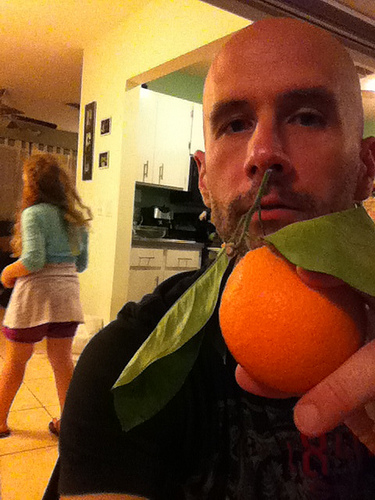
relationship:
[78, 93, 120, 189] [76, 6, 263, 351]
pictures on wall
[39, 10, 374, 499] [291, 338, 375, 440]
man has finger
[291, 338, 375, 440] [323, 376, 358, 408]
finger has ridges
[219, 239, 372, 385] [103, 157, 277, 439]
orange has leaf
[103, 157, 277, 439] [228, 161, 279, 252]
leaf has stem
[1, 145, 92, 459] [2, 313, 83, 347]
woman wears shorts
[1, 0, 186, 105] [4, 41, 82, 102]
ceiling has shadow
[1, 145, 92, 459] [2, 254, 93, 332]
woman wears shirt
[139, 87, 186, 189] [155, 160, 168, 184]
cabinet has handle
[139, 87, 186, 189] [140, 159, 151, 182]
cabinet has handle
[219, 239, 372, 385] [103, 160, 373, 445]
orange has leaves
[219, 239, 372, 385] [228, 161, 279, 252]
orange has stem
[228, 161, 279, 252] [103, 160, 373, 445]
stem has leaves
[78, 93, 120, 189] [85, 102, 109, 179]
pictures have frames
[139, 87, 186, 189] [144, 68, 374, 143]
cabinet attached to wall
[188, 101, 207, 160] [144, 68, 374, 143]
cabinet attached to wall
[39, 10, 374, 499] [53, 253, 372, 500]
man wears shirt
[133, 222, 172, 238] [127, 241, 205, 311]
bowl on counter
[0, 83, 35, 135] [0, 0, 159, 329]
ceiling fan maybe in room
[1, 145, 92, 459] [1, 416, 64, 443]
woman wears sandals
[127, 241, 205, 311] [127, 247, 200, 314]
counter has cabinet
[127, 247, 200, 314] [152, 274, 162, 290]
cabinet has silvertone handle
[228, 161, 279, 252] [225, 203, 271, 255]
stem has branches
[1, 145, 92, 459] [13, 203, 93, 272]
woman wears sweater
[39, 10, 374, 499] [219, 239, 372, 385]
man holds orange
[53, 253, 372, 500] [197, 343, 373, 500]
shirt has pattern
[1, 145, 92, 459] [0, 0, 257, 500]
woman in background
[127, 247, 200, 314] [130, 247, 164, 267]
cabinet has drawer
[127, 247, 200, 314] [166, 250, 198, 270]
cabinet has drawer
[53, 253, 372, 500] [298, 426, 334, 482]
shirt has '8'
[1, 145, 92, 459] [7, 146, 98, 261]
woman has hair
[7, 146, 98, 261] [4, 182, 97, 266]
hair has cascading curls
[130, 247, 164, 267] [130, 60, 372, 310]
drawer in kitchen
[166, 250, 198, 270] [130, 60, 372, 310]
drawer in kitchen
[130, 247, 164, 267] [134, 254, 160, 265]
drawer has handle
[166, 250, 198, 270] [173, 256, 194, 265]
drawer has handle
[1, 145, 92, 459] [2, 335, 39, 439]
woman has leg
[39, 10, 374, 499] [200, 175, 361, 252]
man needs shave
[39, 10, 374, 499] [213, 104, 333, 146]
man has eyes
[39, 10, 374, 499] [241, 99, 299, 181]
man has nose